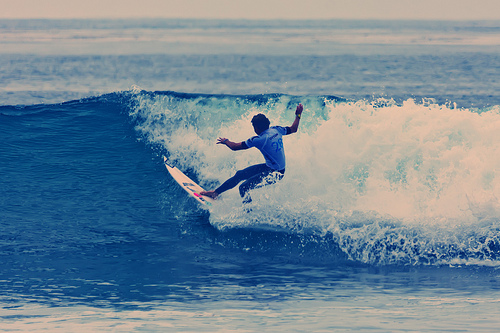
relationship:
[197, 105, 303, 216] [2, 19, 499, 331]
man on a water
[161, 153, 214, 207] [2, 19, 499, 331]
surfboard on water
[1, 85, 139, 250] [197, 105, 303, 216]
unbroken wave before man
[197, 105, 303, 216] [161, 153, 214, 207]
man on surfboard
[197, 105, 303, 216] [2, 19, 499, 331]
man rides a water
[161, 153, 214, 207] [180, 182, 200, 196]
surfboard has printing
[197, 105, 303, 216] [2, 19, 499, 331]
man riding water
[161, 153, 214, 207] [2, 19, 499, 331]
surfboard in water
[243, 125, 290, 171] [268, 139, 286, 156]
top has a 28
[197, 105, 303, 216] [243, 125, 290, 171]
man wears a top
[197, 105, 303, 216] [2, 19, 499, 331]
man in water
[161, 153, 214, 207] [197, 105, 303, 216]
surfboard under man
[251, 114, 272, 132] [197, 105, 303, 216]
head of man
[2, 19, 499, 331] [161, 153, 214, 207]
water under surfboard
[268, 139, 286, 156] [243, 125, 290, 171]
28 on top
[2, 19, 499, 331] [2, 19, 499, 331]
water on water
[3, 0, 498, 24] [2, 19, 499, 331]
sky above water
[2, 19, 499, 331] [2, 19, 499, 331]
water in water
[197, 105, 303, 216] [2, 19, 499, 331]
man surfs on water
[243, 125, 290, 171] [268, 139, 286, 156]
top says number 28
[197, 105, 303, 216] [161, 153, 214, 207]
man on h surfboard